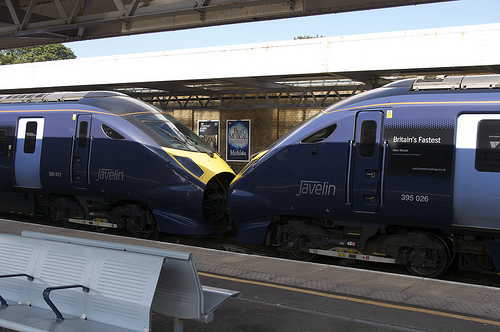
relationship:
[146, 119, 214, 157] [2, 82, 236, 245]
wipers on train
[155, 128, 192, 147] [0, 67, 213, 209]
windshield wiper on train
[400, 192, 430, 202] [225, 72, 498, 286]
number on train engine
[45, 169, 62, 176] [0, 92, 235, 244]
number on train engine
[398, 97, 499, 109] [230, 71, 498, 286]
yellow stripe on train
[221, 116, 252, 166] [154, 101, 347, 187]
poster on wall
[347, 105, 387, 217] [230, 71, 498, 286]
door on train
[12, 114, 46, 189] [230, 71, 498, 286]
door on train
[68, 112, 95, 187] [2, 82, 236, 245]
door on train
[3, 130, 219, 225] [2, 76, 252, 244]
shadow on train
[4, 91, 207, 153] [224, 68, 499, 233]
light on train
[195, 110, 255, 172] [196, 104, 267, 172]
posters hanging on wall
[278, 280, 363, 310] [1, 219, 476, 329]
yellow line across platform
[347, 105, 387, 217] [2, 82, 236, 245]
door of train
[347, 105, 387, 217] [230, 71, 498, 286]
door of train